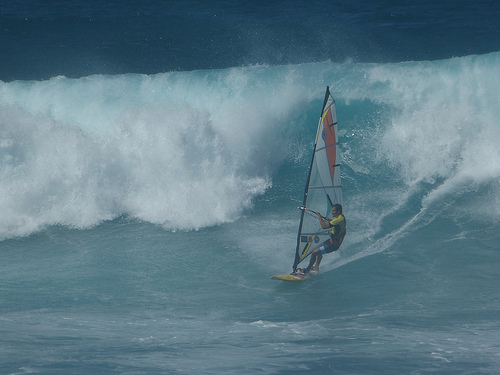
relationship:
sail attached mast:
[291, 84, 344, 268] [291, 89, 329, 272]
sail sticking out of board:
[256, 95, 382, 238] [276, 264, 326, 285]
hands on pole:
[315, 210, 331, 220] [293, 180, 307, 237]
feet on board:
[277, 265, 319, 287] [279, 273, 292, 288]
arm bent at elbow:
[315, 212, 340, 229] [321, 224, 328, 229]